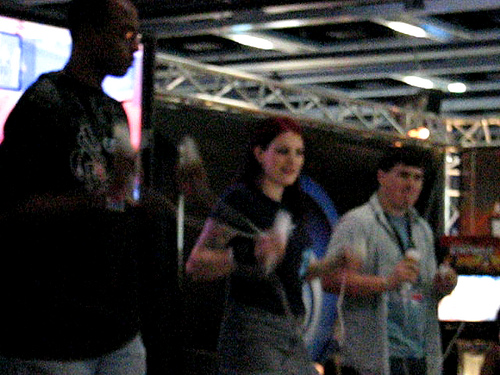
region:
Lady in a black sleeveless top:
[178, 110, 334, 374]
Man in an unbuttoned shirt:
[314, 143, 459, 373]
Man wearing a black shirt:
[0, 69, 150, 364]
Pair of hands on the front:
[315, 238, 465, 303]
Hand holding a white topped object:
[383, 245, 428, 306]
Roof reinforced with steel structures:
[2, 1, 499, 153]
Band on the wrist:
[225, 230, 261, 272]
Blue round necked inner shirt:
[362, 210, 429, 364]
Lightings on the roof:
[220, 11, 475, 106]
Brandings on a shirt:
[37, 78, 139, 237]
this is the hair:
[262, 117, 294, 127]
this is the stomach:
[397, 290, 426, 318]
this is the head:
[371, 147, 421, 205]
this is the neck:
[263, 181, 280, 196]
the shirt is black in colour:
[41, 257, 106, 333]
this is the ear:
[251, 145, 261, 160]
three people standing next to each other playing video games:
[2, 3, 460, 372]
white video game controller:
[257, 205, 297, 281]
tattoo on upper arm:
[204, 220, 232, 251]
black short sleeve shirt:
[205, 177, 315, 320]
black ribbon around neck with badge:
[375, 198, 420, 300]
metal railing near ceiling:
[153, 48, 498, 153]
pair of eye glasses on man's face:
[112, 19, 147, 46]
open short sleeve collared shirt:
[319, 191, 446, 373]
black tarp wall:
[147, 100, 443, 372]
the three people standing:
[0, 0, 457, 370]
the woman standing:
[182, 115, 356, 374]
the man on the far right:
[320, 145, 459, 373]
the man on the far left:
[0, 0, 145, 372]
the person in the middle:
[188, 117, 358, 374]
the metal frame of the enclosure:
[1, 0, 498, 240]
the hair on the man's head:
[379, 147, 431, 171]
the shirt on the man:
[324, 191, 442, 373]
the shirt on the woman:
[208, 184, 305, 319]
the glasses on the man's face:
[117, 28, 143, 43]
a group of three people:
[6, 0, 484, 372]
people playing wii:
[2, 2, 465, 373]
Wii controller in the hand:
[245, 199, 295, 283]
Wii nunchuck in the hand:
[323, 232, 367, 284]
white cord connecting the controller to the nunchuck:
[253, 200, 380, 373]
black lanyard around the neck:
[380, 210, 423, 261]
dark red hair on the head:
[233, 110, 325, 195]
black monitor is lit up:
[422, 268, 498, 331]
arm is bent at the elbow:
[179, 201, 258, 284]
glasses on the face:
[96, 25, 151, 42]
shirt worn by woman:
[210, 173, 311, 317]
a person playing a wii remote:
[355, 121, 490, 300]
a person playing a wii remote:
[67, 21, 157, 218]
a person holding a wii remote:
[216, 99, 317, 279]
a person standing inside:
[340, 148, 432, 300]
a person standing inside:
[231, 123, 321, 358]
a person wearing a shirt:
[217, 151, 332, 341]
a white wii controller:
[262, 210, 292, 270]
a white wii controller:
[396, 242, 418, 299]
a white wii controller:
[437, 262, 451, 292]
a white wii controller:
[105, 125, 135, 165]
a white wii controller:
[166, 143, 213, 188]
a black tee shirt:
[214, 182, 306, 312]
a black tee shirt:
[8, 73, 151, 371]